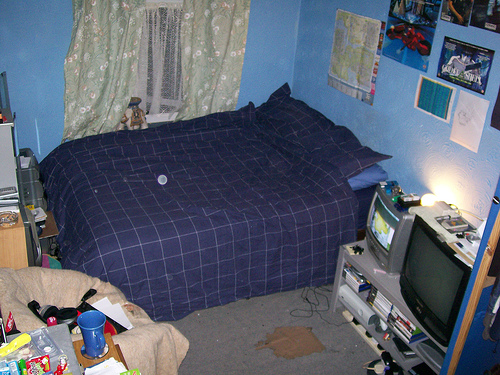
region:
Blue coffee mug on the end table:
[76, 309, 109, 361]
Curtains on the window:
[63, 0, 247, 139]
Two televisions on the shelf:
[361, 183, 476, 348]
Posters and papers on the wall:
[323, 2, 496, 152]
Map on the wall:
[323, 6, 384, 102]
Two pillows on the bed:
[257, 80, 389, 187]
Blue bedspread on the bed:
[42, 101, 360, 321]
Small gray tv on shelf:
[366, 190, 406, 270]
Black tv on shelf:
[397, 215, 462, 340]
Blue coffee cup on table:
[76, 313, 111, 351]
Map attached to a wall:
[330, 17, 384, 105]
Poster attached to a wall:
[435, 36, 490, 92]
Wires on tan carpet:
[289, 283, 345, 320]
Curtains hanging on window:
[64, 3, 246, 133]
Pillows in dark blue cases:
[250, 81, 390, 183]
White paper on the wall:
[453, 90, 490, 155]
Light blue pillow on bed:
[347, 161, 392, 193]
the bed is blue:
[95, 190, 171, 255]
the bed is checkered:
[155, 147, 300, 262]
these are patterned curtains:
[90, 35, 145, 100]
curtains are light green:
[180, 15, 315, 125]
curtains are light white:
[170, 25, 275, 100]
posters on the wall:
[296, 30, 456, 90]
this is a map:
[310, 27, 391, 92]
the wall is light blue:
[370, 102, 470, 179]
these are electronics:
[340, 193, 495, 359]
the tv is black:
[387, 227, 474, 341]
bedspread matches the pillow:
[38, 73, 405, 319]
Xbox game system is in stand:
[337, 279, 378, 336]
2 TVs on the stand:
[354, 180, 487, 362]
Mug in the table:
[73, 308, 115, 369]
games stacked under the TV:
[361, 285, 432, 353]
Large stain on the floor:
[250, 316, 356, 368]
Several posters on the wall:
[377, 5, 497, 212]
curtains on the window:
[63, 11, 273, 135]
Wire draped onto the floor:
[273, 254, 356, 336]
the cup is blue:
[77, 307, 110, 357]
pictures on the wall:
[328, 12, 494, 162]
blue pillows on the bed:
[249, 72, 375, 226]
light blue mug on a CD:
[76, 308, 108, 358]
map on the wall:
[326, 7, 384, 107]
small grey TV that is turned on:
[366, 188, 414, 275]